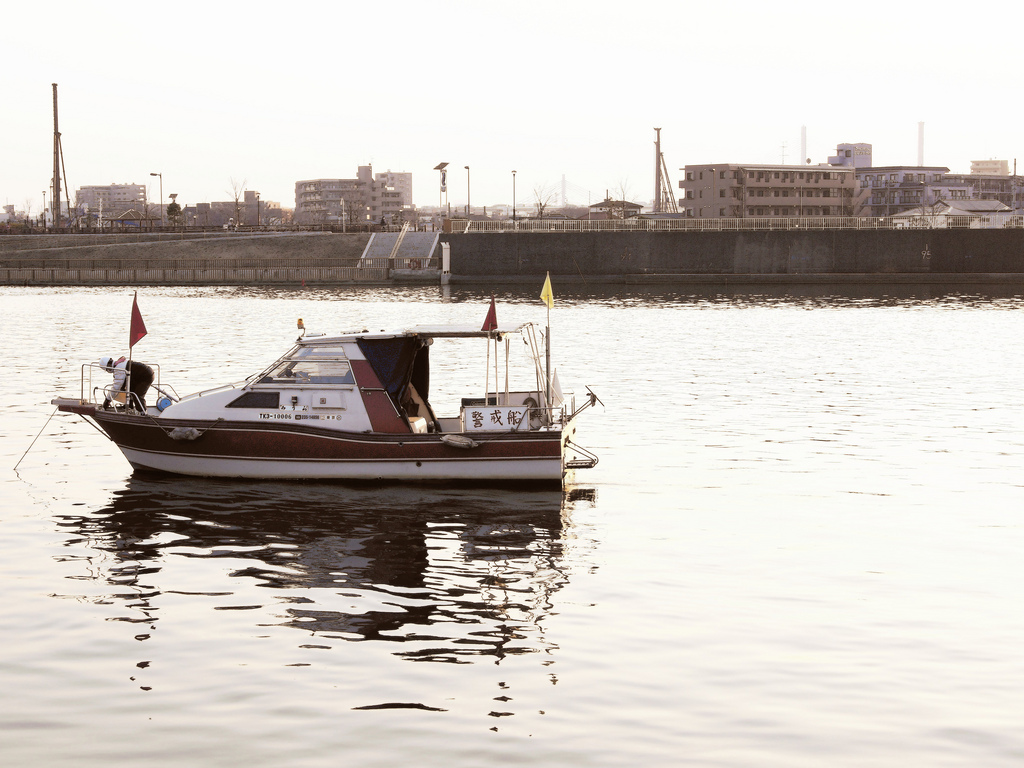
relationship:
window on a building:
[719, 166, 726, 180] [678, 162, 874, 230]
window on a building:
[716, 182, 727, 198] [678, 162, 874, 230]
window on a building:
[758, 190, 765, 197] [678, 162, 874, 230]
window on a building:
[827, 184, 841, 198] [636, 138, 1006, 260]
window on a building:
[932, 187, 943, 203] [690, 155, 939, 242]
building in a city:
[828, 142, 1022, 228] [688, 163, 1017, 222]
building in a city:
[828, 142, 1022, 228] [664, 161, 1014, 224]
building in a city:
[967, 161, 1009, 174] [671, 168, 1021, 229]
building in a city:
[588, 199, 642, 225] [85, 155, 980, 238]